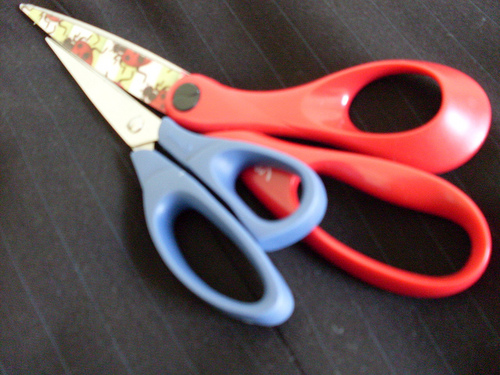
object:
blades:
[43, 34, 168, 148]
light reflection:
[437, 102, 486, 152]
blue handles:
[128, 148, 295, 331]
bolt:
[124, 115, 147, 134]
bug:
[60, 35, 95, 66]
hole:
[227, 157, 309, 228]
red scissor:
[18, 2, 495, 302]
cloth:
[0, 0, 499, 375]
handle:
[165, 57, 494, 175]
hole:
[296, 169, 477, 276]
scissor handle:
[207, 125, 497, 300]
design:
[109, 41, 154, 84]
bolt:
[167, 80, 200, 111]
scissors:
[42, 32, 329, 328]